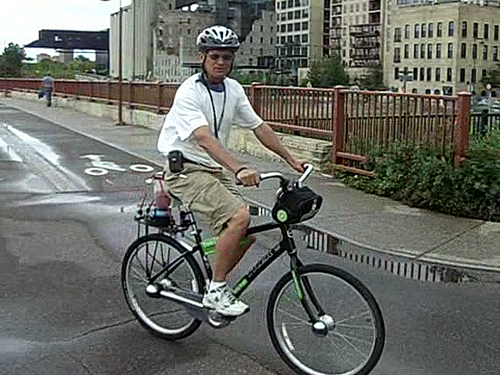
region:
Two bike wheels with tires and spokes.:
[118, 232, 388, 374]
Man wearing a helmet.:
[196, 25, 241, 83]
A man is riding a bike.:
[117, 18, 383, 370]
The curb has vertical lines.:
[256, 205, 463, 287]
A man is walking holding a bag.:
[35, 70, 55, 106]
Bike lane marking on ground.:
[80, 150, 152, 175]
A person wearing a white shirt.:
[155, 71, 306, 167]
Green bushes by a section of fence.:
[338, 86, 496, 224]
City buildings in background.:
[25, 0, 496, 101]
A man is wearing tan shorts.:
[163, 155, 250, 231]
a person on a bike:
[115, 8, 412, 370]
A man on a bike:
[103, 18, 413, 370]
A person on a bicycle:
[100, 13, 428, 374]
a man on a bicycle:
[98, 21, 420, 373]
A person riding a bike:
[114, 19, 396, 374]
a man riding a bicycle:
[125, 13, 402, 374]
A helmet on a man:
[190, 24, 245, 58]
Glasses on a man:
[205, 50, 234, 64]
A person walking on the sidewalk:
[31, 68, 67, 110]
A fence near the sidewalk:
[13, 68, 469, 161]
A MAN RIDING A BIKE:
[116, 22, 391, 373]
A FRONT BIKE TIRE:
[263, 260, 390, 373]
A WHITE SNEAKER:
[196, 275, 253, 322]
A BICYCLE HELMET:
[191, 22, 245, 54]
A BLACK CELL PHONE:
[163, 146, 187, 176]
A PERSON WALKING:
[34, 65, 61, 110]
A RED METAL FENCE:
[257, 78, 479, 176]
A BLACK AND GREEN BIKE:
[119, 157, 391, 374]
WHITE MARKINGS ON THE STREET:
[79, 143, 153, 185]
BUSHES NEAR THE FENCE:
[374, 128, 496, 225]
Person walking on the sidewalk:
[35, 69, 55, 106]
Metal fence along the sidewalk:
[3, 74, 472, 182]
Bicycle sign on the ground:
[81, 152, 156, 182]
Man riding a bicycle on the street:
[157, 27, 307, 319]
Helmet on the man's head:
[194, 23, 241, 51]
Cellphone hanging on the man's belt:
[166, 149, 186, 173]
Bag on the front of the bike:
[272, 187, 322, 227]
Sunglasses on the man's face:
[203, 50, 234, 61]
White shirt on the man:
[155, 75, 261, 170]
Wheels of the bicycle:
[119, 234, 385, 374]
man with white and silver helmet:
[171, 24, 274, 220]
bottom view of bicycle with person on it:
[125, 197, 379, 367]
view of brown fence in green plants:
[321, 86, 483, 201]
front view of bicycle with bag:
[268, 167, 380, 374]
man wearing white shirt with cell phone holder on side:
[166, 11, 283, 189]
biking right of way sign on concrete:
[57, 133, 146, 198]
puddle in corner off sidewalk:
[347, 192, 482, 272]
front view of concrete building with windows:
[392, 4, 468, 94]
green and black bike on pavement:
[148, 229, 369, 349]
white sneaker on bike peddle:
[190, 273, 271, 344]